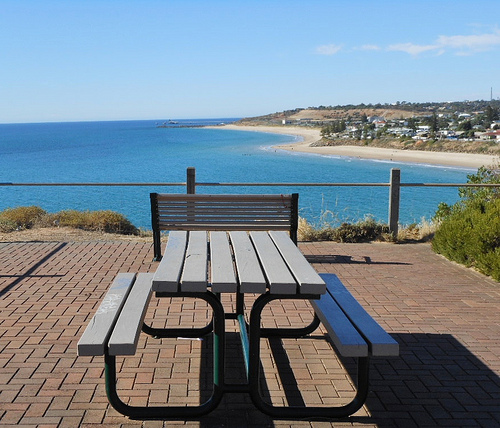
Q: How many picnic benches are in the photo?
A: One.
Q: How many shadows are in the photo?
A: Three.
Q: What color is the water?
A: Blue.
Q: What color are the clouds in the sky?
A: White.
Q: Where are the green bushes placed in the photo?
A: On the right side.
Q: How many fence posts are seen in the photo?
A: Two.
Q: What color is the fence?
A: Brown.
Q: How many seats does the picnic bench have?
A: Two.